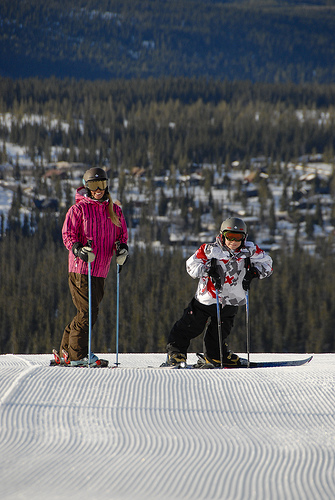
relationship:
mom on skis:
[48, 163, 131, 369] [167, 343, 314, 380]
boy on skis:
[161, 210, 286, 360] [167, 343, 314, 380]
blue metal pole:
[81, 263, 97, 366] [109, 258, 124, 364]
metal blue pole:
[81, 238, 95, 254] [109, 258, 124, 364]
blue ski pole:
[81, 263, 97, 366] [109, 258, 124, 364]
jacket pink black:
[62, 196, 149, 275] [69, 240, 90, 258]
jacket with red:
[62, 196, 149, 275] [199, 277, 222, 298]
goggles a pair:
[83, 176, 113, 192] [223, 229, 244, 241]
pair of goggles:
[223, 229, 244, 241] [83, 176, 113, 192]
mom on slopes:
[48, 163, 131, 369] [8, 341, 334, 495]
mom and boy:
[44, 154, 142, 380] [165, 215, 275, 365]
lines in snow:
[17, 356, 103, 469] [11, 337, 334, 497]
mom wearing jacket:
[48, 163, 131, 369] [62, 187, 128, 276]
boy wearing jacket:
[165, 215, 275, 365] [62, 187, 128, 276]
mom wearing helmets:
[48, 163, 131, 369] [80, 165, 250, 232]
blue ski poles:
[81, 263, 97, 366] [76, 237, 133, 373]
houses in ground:
[42, 158, 155, 183] [3, 126, 331, 251]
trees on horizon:
[1, 73, 335, 107] [5, 6, 332, 67]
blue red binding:
[81, 263, 97, 366] [70, 239, 93, 261]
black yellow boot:
[69, 240, 90, 258] [163, 347, 193, 370]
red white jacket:
[199, 277, 222, 298] [62, 187, 128, 276]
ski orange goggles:
[239, 347, 316, 372] [83, 176, 113, 192]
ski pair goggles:
[239, 347, 316, 372] [83, 176, 113, 192]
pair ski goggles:
[223, 229, 244, 241] [83, 176, 113, 192]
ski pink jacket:
[239, 347, 316, 372] [62, 196, 149, 275]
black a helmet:
[69, 240, 90, 258] [213, 214, 251, 238]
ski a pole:
[239, 347, 316, 372] [109, 258, 124, 364]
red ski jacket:
[199, 277, 222, 298] [62, 196, 149, 275]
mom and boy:
[48, 163, 131, 369] [165, 215, 275, 365]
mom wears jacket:
[48, 163, 131, 369] [62, 196, 149, 275]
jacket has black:
[62, 196, 149, 275] [69, 240, 90, 258]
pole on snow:
[109, 258, 124, 364] [11, 337, 334, 497]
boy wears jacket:
[165, 215, 275, 365] [62, 187, 128, 276]